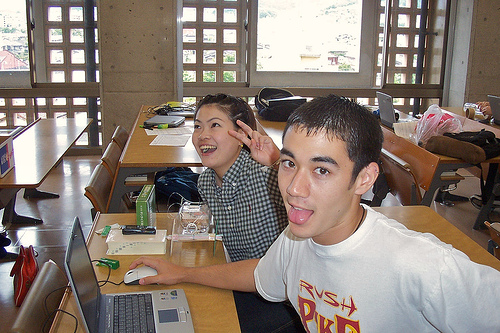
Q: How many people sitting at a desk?
A: 2.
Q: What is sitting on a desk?
A: A laptop.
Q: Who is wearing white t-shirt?
A: The man.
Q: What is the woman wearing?
A: A checkered shirt.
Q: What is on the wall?
A: A window.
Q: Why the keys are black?
A: For design.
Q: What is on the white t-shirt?
A: Red markings.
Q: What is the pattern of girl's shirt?
A: Plaid.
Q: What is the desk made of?
A: Wood.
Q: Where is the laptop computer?
A: On desk.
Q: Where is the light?
A: In window.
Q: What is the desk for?
A: Studies.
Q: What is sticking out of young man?
A: Tongue.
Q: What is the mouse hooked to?
A: Laptop.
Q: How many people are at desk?
A: Two.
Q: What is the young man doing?
A: Sticking out tongue.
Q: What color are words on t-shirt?
A: Red and yellow.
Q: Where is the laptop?
A: On table.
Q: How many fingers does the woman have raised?
A: Two.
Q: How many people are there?
A: 2.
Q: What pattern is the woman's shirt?
A: Checked.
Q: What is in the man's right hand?
A: Mouse.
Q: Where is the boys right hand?
A: On the mouse.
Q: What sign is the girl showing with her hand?
A: Peace sign.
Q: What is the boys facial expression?
A: Tongue sticking out.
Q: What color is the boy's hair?
A: Black.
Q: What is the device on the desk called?
A: Computer.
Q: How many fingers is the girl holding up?
A: Two.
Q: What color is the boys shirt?
A: White.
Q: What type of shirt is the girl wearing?
A: Plaid.